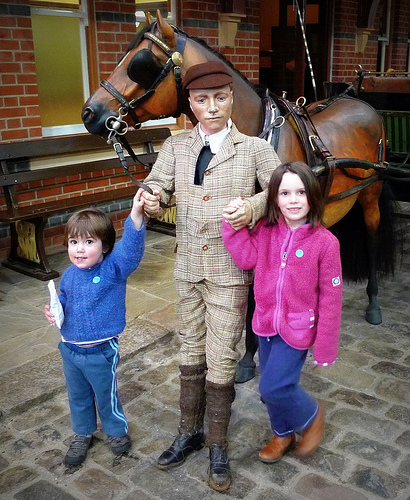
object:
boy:
[41, 181, 154, 475]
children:
[210, 156, 348, 464]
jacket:
[218, 213, 346, 369]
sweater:
[51, 210, 154, 354]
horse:
[84, 10, 393, 325]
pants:
[53, 342, 133, 439]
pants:
[254, 329, 322, 438]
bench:
[1, 125, 188, 283]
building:
[0, 3, 408, 267]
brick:
[0, 83, 26, 97]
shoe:
[60, 431, 94, 470]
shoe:
[294, 401, 331, 460]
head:
[265, 151, 325, 226]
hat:
[180, 60, 237, 92]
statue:
[134, 51, 295, 500]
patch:
[124, 44, 167, 92]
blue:
[39, 211, 151, 441]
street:
[0, 278, 408, 495]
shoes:
[105, 422, 136, 457]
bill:
[184, 71, 237, 92]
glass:
[28, 9, 102, 140]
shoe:
[256, 428, 297, 467]